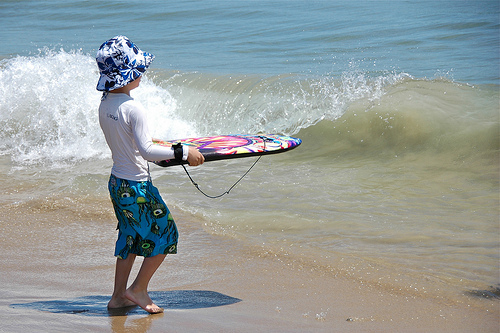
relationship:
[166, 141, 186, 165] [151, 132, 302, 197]
strap on board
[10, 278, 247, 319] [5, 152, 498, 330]
shadow on sand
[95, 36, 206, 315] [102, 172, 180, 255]
boy wearing shorts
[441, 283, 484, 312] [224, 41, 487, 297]
shadow in water